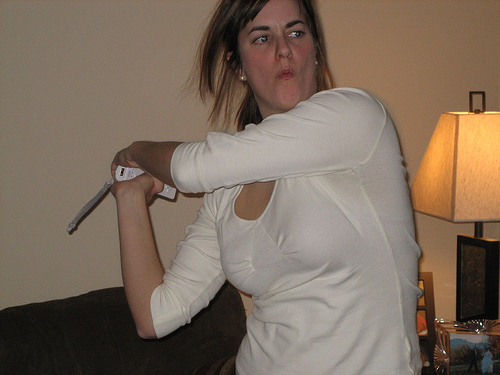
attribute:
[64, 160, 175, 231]
remote — nintendo, wii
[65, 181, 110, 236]
strap — wii, grey, nintendo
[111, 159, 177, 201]
wii — nintendo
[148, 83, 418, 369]
shirt — white, three, sleeve, quarter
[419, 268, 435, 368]
chair — wooden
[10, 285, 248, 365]
couch — dark, colored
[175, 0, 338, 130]
hair — medium length, blonde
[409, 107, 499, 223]
shade — white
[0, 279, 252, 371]
sofa — brown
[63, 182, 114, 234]
strap — gray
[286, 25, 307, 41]
eye — brown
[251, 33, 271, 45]
eye — brown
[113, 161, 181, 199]
wii remote — white